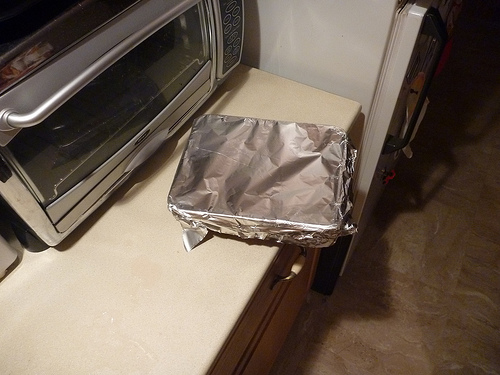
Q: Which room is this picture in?
A: It is at the kitchen.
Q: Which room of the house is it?
A: It is a kitchen.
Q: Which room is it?
A: It is a kitchen.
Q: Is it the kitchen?
A: Yes, it is the kitchen.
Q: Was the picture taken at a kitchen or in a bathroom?
A: It was taken at a kitchen.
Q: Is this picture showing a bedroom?
A: No, the picture is showing a kitchen.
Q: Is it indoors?
A: Yes, it is indoors.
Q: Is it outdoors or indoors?
A: It is indoors.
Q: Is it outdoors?
A: No, it is indoors.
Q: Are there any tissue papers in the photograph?
A: No, there are no tissue papers.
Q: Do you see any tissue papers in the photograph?
A: No, there are no tissue papers.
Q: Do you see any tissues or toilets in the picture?
A: No, there are no tissues or toilets.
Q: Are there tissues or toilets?
A: No, there are no tissues or toilets.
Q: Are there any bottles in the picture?
A: No, there are no bottles.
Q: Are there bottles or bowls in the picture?
A: No, there are no bottles or bowls.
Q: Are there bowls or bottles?
A: No, there are no bottles or bowls.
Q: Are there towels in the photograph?
A: No, there are no towels.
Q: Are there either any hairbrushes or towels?
A: No, there are no towels or hairbrushes.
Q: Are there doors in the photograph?
A: Yes, there is a door.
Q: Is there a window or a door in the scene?
A: Yes, there is a door.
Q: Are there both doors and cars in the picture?
A: No, there is a door but no cars.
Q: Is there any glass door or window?
A: Yes, there is a glass door.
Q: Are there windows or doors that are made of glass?
A: Yes, the door is made of glass.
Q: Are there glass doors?
A: Yes, there is a door that is made of glass.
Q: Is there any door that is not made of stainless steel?
A: Yes, there is a door that is made of glass.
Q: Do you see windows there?
A: No, there are no windows.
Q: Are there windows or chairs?
A: No, there are no windows or chairs.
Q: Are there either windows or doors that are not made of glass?
A: No, there is a door but it is made of glass.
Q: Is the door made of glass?
A: Yes, the door is made of glass.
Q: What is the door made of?
A: The door is made of glass.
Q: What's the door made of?
A: The door is made of glass.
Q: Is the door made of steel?
A: No, the door is made of glass.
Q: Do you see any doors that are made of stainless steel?
A: No, there is a door but it is made of glass.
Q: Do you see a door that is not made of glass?
A: No, there is a door but it is made of glass.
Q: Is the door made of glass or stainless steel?
A: The door is made of glass.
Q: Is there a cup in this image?
A: No, there are no cups.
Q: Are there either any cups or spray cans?
A: No, there are no cups or spray cans.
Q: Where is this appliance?
A: The appliance is in the kitchen.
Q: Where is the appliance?
A: The appliance is in the kitchen.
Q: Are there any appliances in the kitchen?
A: Yes, there is an appliance in the kitchen.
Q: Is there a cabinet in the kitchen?
A: No, there is an appliance in the kitchen.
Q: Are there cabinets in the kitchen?
A: No, there is an appliance in the kitchen.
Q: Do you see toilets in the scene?
A: No, there are no toilets.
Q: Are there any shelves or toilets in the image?
A: No, there are no toilets or shelves.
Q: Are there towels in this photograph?
A: No, there are no towels.